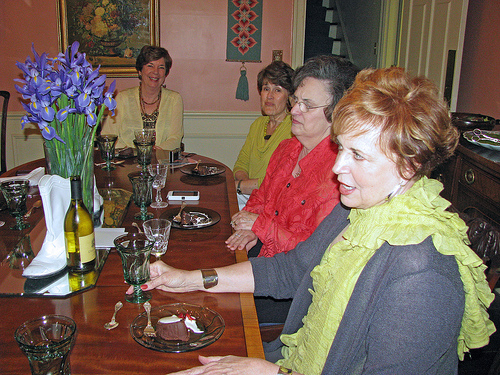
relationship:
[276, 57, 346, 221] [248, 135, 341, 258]
woman wears red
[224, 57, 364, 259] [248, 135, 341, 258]
woman wears red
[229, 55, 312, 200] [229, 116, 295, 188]
woman wears green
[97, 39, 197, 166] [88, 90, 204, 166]
woman wears yellow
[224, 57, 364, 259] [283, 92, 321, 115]
woman wearing glasses